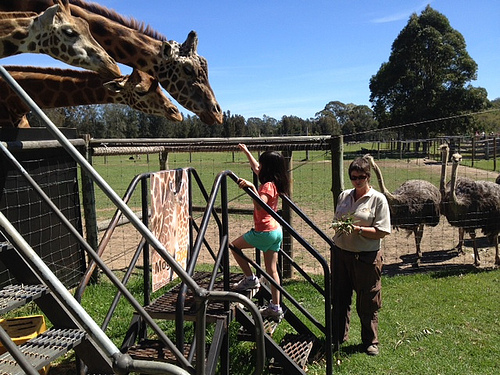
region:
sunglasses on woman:
[348, 175, 372, 184]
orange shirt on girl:
[255, 185, 283, 228]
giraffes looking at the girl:
[116, 25, 242, 128]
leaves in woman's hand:
[323, 218, 358, 233]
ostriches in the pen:
[436, 141, 498, 270]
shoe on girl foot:
[234, 278, 259, 290]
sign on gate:
[135, 173, 191, 288]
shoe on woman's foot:
[358, 340, 384, 356]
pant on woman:
[321, 248, 384, 347]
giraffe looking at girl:
[22, 5, 135, 86]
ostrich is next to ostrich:
[362, 152, 442, 269]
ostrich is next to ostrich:
[438, 145, 498, 266]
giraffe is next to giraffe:
[0, 0, 227, 128]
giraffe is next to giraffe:
[0, 3, 120, 78]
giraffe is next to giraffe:
[0, 66, 185, 123]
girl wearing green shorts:
[222, 142, 286, 320]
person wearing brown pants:
[328, 156, 386, 350]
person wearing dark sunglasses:
[323, 155, 387, 356]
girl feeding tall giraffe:
[226, 138, 284, 322]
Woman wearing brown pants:
[322, 151, 389, 357]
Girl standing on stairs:
[221, 135, 296, 327]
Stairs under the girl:
[154, 252, 351, 373]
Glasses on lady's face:
[347, 158, 372, 187]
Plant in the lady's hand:
[333, 216, 364, 248]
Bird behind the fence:
[358, 151, 442, 270]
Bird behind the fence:
[447, 151, 499, 266]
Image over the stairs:
[134, 171, 200, 297]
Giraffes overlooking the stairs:
[1, 1, 273, 189]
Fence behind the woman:
[79, 136, 497, 283]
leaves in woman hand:
[326, 213, 363, 238]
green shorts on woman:
[247, 225, 285, 250]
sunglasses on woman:
[342, 173, 374, 180]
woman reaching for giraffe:
[223, 140, 289, 317]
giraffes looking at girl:
[91, 5, 242, 121]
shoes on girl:
[234, 274, 259, 289]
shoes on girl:
[257, 303, 284, 317]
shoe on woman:
[367, 337, 384, 358]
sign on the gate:
[150, 173, 192, 291]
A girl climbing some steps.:
[210, 138, 326, 355]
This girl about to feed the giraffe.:
[155, 25, 287, 320]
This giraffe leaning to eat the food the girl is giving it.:
[148, 18, 229, 163]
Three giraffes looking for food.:
[17, 5, 226, 130]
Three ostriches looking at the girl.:
[358, 142, 497, 271]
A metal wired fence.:
[95, 147, 489, 262]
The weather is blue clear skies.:
[205, 13, 365, 106]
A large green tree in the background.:
[363, 14, 487, 145]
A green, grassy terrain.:
[403, 284, 490, 364]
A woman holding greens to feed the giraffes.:
[312, 148, 395, 363]